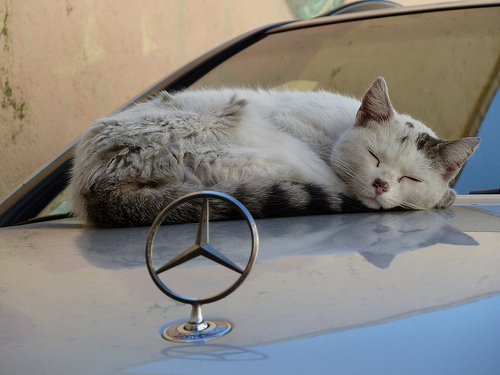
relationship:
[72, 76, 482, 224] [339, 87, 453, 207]
cat with head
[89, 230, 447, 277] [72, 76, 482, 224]
reflection of cat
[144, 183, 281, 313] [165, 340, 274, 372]
insignia and reflection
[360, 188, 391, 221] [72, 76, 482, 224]
mouth of cat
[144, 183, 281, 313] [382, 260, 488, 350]
insignia on car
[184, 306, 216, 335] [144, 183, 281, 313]
small stand for insignia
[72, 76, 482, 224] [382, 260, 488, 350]
cat on car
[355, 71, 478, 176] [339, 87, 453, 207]
ears on head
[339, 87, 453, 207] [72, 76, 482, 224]
head of cat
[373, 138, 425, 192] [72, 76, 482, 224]
eyes of cat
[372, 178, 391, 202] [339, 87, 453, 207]
nose on head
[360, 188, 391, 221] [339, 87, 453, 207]
mouth on head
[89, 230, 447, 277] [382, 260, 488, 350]
reflection on car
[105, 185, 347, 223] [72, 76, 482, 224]
tail of cat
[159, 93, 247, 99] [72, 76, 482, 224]
fur of cat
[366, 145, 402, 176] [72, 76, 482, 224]
eye of cat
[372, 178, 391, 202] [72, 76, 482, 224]
nose of cat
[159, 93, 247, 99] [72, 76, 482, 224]
fur on cat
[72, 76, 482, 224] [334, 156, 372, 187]
cat has whiskers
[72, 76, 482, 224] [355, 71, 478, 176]
cat has ears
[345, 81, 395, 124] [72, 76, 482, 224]
ear of a cat